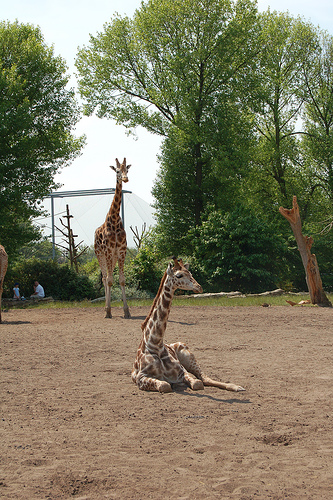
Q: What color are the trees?
A: Green.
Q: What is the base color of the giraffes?
A: Tan.